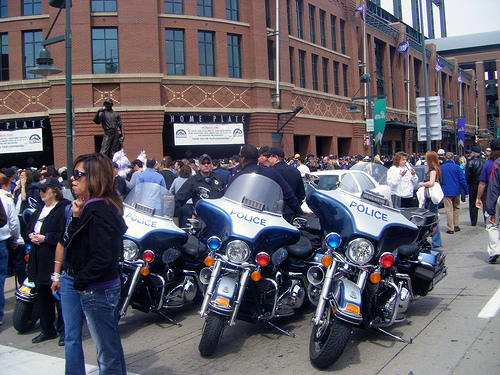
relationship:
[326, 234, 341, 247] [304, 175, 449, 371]
light on motorcycle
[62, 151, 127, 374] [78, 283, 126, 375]
woman wearing jeans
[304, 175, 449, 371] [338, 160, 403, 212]
motorcycle has a windshield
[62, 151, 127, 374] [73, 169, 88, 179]
woman wearing glasses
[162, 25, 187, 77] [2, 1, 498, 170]
window on building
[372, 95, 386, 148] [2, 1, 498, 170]
banner next to building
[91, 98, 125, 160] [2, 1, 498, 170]
statue next to building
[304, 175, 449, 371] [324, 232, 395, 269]
motorcycle has headlights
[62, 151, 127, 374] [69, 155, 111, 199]
woman has a head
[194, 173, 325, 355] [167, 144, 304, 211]
motorcycle used by police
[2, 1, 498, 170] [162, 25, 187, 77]
building has a window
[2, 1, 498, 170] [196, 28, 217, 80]
building has a window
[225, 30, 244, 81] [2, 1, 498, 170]
window on building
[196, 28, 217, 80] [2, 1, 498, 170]
window on building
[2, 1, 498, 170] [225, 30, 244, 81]
building has a window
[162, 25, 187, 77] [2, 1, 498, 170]
window part of building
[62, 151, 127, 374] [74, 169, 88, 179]
woman wearing glasses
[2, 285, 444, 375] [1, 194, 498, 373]
shadows are on ground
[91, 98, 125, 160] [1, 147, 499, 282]
statue standing above crowd